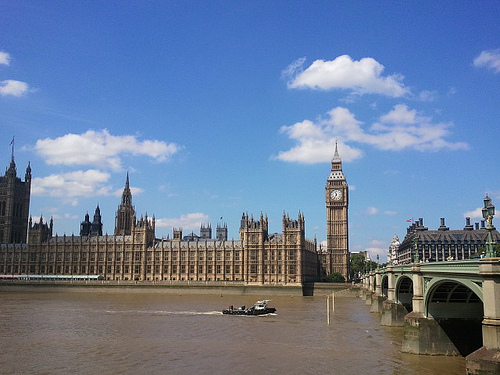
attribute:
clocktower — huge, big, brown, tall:
[325, 137, 349, 281]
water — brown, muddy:
[1, 282, 467, 374]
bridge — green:
[358, 216, 498, 374]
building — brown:
[0, 158, 33, 245]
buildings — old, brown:
[0, 148, 499, 280]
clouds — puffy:
[272, 55, 467, 164]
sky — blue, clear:
[1, 1, 499, 264]